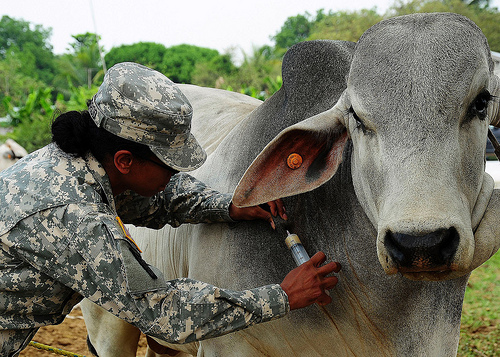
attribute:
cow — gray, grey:
[79, 14, 499, 356]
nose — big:
[379, 223, 463, 279]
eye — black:
[472, 88, 489, 118]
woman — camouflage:
[1, 60, 342, 356]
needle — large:
[270, 213, 332, 305]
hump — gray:
[273, 39, 351, 97]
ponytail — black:
[48, 110, 91, 160]